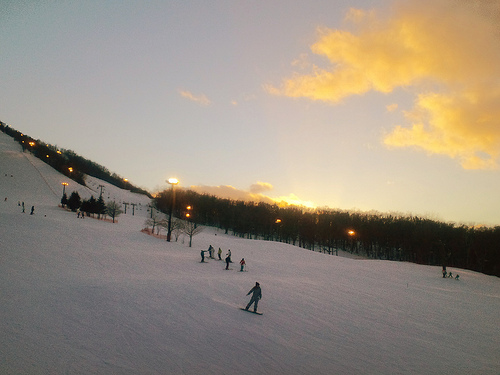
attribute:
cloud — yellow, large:
[271, 3, 497, 181]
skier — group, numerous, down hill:
[239, 257, 246, 272]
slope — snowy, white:
[1, 132, 499, 374]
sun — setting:
[269, 194, 304, 209]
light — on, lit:
[166, 175, 181, 187]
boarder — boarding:
[241, 280, 263, 318]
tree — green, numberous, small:
[95, 192, 107, 219]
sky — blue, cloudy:
[2, 2, 499, 227]